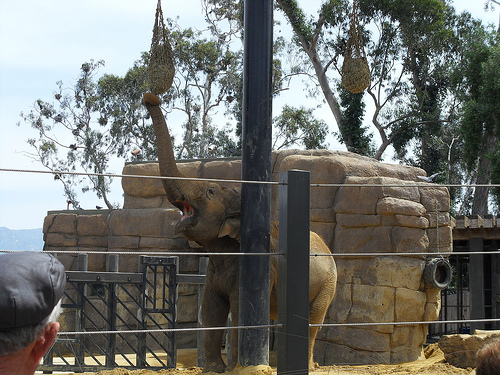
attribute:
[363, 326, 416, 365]
hay — sack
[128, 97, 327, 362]
elephant — adult, standing, dirty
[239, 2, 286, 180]
pole — brown, black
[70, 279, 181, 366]
bars — metal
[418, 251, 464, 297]
tire — black, hanging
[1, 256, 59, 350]
hat — leather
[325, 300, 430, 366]
rock — formation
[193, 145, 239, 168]
roofing — wood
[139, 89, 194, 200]
trunk — upwards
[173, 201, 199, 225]
mouth — open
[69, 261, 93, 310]
gate — iron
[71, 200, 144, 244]
boulders — stone